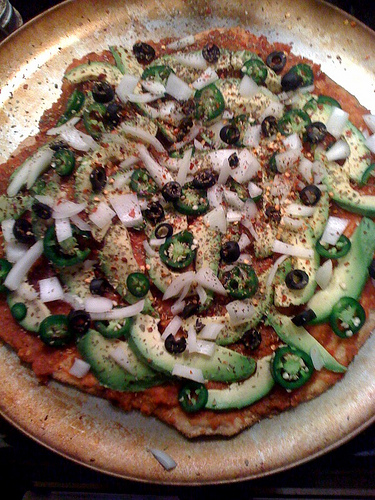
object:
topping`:
[126, 103, 315, 363]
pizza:
[0, 25, 375, 443]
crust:
[26, 406, 128, 498]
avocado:
[195, 354, 277, 412]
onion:
[315, 259, 333, 290]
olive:
[290, 267, 302, 285]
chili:
[23, 344, 69, 369]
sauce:
[40, 83, 81, 145]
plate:
[7, 9, 102, 108]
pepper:
[102, 170, 169, 251]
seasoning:
[148, 137, 213, 217]